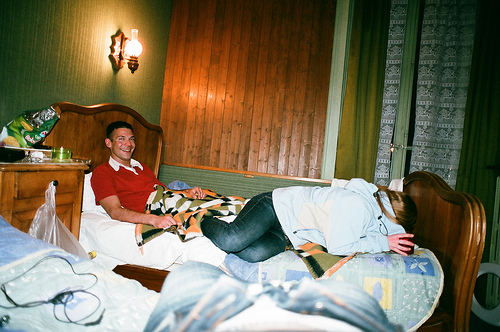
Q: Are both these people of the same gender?
A: No, they are both male and female.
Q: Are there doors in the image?
A: Yes, there is a door.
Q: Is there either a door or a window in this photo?
A: Yes, there is a door.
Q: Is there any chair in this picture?
A: No, there are no chairs.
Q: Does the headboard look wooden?
A: Yes, the headboard is wooden.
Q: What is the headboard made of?
A: The headboard is made of wood.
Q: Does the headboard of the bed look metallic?
A: No, the headboard is wooden.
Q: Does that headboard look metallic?
A: No, the headboard is wooden.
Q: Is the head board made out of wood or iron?
A: The head board is made of wood.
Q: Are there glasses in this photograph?
A: No, there are no glasses.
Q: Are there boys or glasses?
A: No, there are no glasses or boys.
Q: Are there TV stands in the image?
A: No, there are no TV stands.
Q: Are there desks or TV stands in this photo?
A: No, there are no TV stands or desks.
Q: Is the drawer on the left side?
A: Yes, the drawer is on the left of the image.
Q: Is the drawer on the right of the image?
A: No, the drawer is on the left of the image.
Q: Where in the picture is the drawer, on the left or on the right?
A: The drawer is on the left of the image.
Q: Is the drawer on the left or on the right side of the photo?
A: The drawer is on the left of the image.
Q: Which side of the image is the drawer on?
A: The drawer is on the left of the image.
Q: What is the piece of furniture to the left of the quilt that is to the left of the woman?
A: The piece of furniture is a drawer.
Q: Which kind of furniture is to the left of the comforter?
A: The piece of furniture is a drawer.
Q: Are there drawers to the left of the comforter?
A: Yes, there is a drawer to the left of the comforter.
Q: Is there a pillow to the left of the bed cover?
A: No, there is a drawer to the left of the bed cover.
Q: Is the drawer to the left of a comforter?
A: Yes, the drawer is to the left of a comforter.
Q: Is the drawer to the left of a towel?
A: No, the drawer is to the left of a comforter.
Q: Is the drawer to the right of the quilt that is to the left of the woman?
A: No, the drawer is to the left of the bed cover.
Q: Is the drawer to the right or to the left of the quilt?
A: The drawer is to the left of the quilt.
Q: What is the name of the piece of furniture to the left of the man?
A: The piece of furniture is a drawer.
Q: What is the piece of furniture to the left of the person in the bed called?
A: The piece of furniture is a drawer.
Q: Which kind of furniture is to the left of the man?
A: The piece of furniture is a drawer.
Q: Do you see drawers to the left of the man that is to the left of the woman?
A: Yes, there is a drawer to the left of the man.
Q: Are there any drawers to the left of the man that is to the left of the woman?
A: Yes, there is a drawer to the left of the man.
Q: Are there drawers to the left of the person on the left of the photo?
A: Yes, there is a drawer to the left of the man.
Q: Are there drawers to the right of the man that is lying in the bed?
A: No, the drawer is to the left of the man.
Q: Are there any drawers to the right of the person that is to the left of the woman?
A: No, the drawer is to the left of the man.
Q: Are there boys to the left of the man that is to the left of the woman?
A: No, there is a drawer to the left of the man.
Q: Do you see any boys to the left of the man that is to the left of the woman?
A: No, there is a drawer to the left of the man.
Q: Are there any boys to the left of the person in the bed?
A: No, there is a drawer to the left of the man.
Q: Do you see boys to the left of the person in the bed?
A: No, there is a drawer to the left of the man.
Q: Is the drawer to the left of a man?
A: Yes, the drawer is to the left of a man.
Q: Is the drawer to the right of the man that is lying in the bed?
A: No, the drawer is to the left of the man.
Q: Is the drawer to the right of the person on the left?
A: No, the drawer is to the left of the man.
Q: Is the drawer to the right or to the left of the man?
A: The drawer is to the left of the man.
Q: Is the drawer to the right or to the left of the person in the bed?
A: The drawer is to the left of the man.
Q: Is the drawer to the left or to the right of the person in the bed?
A: The drawer is to the left of the man.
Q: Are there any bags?
A: Yes, there is a bag.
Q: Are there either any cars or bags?
A: Yes, there is a bag.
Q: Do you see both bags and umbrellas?
A: No, there is a bag but no umbrellas.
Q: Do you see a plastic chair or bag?
A: Yes, there is a plastic bag.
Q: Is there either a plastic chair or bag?
A: Yes, there is a plastic bag.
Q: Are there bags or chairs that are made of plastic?
A: Yes, the bag is made of plastic.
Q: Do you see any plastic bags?
A: Yes, there is a bag that is made of plastic.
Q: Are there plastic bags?
A: Yes, there is a bag that is made of plastic.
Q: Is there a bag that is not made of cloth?
A: Yes, there is a bag that is made of plastic.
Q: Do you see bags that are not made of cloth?
A: Yes, there is a bag that is made of plastic.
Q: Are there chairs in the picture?
A: No, there are no chairs.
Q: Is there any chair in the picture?
A: No, there are no chairs.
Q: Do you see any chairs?
A: No, there are no chairs.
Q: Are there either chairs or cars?
A: No, there are no chairs or cars.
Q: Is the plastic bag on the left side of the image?
A: Yes, the bag is on the left of the image.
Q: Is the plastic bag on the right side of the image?
A: No, the bag is on the left of the image.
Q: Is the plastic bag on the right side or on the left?
A: The bag is on the left of the image.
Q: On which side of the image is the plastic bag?
A: The bag is on the left of the image.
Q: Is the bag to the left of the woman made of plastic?
A: Yes, the bag is made of plastic.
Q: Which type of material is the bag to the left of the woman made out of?
A: The bag is made of plastic.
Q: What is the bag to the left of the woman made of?
A: The bag is made of plastic.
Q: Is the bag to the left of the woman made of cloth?
A: No, the bag is made of plastic.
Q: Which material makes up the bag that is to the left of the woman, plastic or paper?
A: The bag is made of plastic.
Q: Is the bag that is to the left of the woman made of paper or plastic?
A: The bag is made of plastic.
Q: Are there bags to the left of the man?
A: Yes, there is a bag to the left of the man.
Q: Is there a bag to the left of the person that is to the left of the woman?
A: Yes, there is a bag to the left of the man.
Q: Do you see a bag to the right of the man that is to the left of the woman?
A: No, the bag is to the left of the man.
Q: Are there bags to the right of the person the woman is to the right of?
A: No, the bag is to the left of the man.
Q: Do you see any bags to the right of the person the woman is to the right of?
A: No, the bag is to the left of the man.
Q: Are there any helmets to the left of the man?
A: No, there is a bag to the left of the man.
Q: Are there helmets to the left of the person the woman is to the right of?
A: No, there is a bag to the left of the man.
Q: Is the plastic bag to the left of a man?
A: Yes, the bag is to the left of a man.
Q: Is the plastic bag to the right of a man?
A: No, the bag is to the left of a man.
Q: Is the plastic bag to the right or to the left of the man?
A: The bag is to the left of the man.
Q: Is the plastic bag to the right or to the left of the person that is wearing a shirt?
A: The bag is to the left of the man.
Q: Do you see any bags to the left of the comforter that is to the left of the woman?
A: Yes, there is a bag to the left of the comforter.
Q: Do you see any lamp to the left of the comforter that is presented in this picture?
A: No, there is a bag to the left of the comforter.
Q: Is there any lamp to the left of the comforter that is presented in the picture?
A: No, there is a bag to the left of the comforter.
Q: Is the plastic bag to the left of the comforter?
A: Yes, the bag is to the left of the comforter.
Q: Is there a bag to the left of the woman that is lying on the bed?
A: Yes, there is a bag to the left of the woman.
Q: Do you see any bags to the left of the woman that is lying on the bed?
A: Yes, there is a bag to the left of the woman.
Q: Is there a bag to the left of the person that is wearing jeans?
A: Yes, there is a bag to the left of the woman.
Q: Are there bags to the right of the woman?
A: No, the bag is to the left of the woman.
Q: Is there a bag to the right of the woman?
A: No, the bag is to the left of the woman.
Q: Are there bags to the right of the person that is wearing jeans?
A: No, the bag is to the left of the woman.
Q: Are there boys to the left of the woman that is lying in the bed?
A: No, there is a bag to the left of the woman.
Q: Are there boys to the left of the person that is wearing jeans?
A: No, there is a bag to the left of the woman.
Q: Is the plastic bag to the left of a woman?
A: Yes, the bag is to the left of a woman.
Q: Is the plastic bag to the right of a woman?
A: No, the bag is to the left of a woman.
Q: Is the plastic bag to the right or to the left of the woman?
A: The bag is to the left of the woman.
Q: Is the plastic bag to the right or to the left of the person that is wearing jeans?
A: The bag is to the left of the woman.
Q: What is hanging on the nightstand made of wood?
A: The bag is hanging on the nightstand.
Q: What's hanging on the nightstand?
A: The bag is hanging on the nightstand.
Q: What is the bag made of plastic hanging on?
A: The bag is hanging on the nightstand.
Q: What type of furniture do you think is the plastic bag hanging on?
A: The bag is hanging on the nightstand.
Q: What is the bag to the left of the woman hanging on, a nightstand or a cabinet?
A: The bag is hanging on a nightstand.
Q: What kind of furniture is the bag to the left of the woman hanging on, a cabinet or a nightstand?
A: The bag is hanging on a nightstand.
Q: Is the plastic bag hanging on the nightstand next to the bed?
A: Yes, the bag is hanging on the nightstand.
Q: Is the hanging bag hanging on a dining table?
A: No, the bag is hanging on the nightstand.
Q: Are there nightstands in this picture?
A: Yes, there is a nightstand.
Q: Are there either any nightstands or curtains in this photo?
A: Yes, there is a nightstand.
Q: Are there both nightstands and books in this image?
A: No, there is a nightstand but no books.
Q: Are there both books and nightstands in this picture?
A: No, there is a nightstand but no books.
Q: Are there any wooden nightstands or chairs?
A: Yes, there is a wood nightstand.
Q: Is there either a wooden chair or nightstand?
A: Yes, there is a wood nightstand.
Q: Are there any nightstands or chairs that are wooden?
A: Yes, the nightstand is wooden.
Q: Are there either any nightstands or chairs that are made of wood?
A: Yes, the nightstand is made of wood.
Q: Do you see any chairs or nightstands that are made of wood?
A: Yes, the nightstand is made of wood.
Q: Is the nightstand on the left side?
A: Yes, the nightstand is on the left of the image.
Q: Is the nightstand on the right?
A: No, the nightstand is on the left of the image.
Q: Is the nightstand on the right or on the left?
A: The nightstand is on the left of the image.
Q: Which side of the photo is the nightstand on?
A: The nightstand is on the left of the image.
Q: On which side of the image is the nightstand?
A: The nightstand is on the left of the image.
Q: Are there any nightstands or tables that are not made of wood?
A: No, there is a nightstand but it is made of wood.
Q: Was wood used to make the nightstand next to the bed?
A: Yes, the nightstand is made of wood.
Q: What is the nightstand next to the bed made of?
A: The nightstand is made of wood.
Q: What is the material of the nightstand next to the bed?
A: The nightstand is made of wood.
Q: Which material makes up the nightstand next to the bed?
A: The nightstand is made of wood.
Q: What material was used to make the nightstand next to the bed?
A: The nightstand is made of wood.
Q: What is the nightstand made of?
A: The nightstand is made of wood.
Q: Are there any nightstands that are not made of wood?
A: No, there is a nightstand but it is made of wood.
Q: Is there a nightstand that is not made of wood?
A: No, there is a nightstand but it is made of wood.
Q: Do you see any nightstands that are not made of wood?
A: No, there is a nightstand but it is made of wood.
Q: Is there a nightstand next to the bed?
A: Yes, there is a nightstand next to the bed.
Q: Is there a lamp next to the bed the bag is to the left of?
A: No, there is a nightstand next to the bed.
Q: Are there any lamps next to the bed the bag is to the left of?
A: No, there is a nightstand next to the bed.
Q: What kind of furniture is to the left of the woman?
A: The piece of furniture is a nightstand.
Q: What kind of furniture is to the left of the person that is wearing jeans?
A: The piece of furniture is a nightstand.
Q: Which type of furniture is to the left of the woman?
A: The piece of furniture is a nightstand.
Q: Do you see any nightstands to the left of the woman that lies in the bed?
A: Yes, there is a nightstand to the left of the woman.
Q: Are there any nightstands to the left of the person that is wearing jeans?
A: Yes, there is a nightstand to the left of the woman.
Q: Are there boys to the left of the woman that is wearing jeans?
A: No, there is a nightstand to the left of the woman.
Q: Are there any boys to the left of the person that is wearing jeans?
A: No, there is a nightstand to the left of the woman.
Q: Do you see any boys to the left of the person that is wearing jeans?
A: No, there is a nightstand to the left of the woman.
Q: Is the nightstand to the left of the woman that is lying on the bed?
A: Yes, the nightstand is to the left of the woman.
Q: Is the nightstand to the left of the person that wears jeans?
A: Yes, the nightstand is to the left of the woman.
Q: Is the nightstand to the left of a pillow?
A: No, the nightstand is to the left of the woman.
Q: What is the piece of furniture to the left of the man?
A: The piece of furniture is a nightstand.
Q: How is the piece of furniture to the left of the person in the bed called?
A: The piece of furniture is a nightstand.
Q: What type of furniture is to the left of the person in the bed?
A: The piece of furniture is a nightstand.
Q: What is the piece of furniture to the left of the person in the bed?
A: The piece of furniture is a nightstand.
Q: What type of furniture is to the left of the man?
A: The piece of furniture is a nightstand.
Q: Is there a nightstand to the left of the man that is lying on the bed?
A: Yes, there is a nightstand to the left of the man.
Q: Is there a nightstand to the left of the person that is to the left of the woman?
A: Yes, there is a nightstand to the left of the man.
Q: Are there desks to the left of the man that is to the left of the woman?
A: No, there is a nightstand to the left of the man.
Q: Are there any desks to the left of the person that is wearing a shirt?
A: No, there is a nightstand to the left of the man.